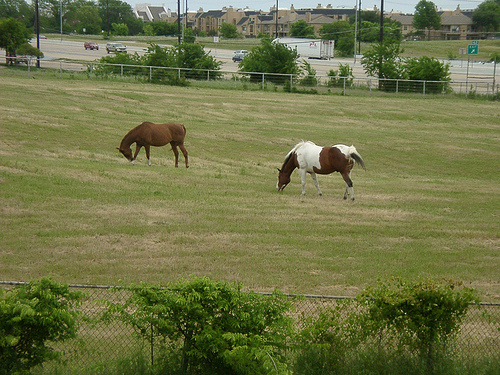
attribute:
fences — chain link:
[1, 275, 500, 368]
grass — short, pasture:
[2, 70, 496, 296]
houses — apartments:
[129, 2, 486, 35]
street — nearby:
[1, 36, 497, 93]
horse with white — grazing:
[272, 138, 370, 201]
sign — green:
[460, 40, 483, 67]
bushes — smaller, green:
[90, 42, 447, 85]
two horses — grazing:
[117, 115, 368, 201]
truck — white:
[262, 34, 334, 61]